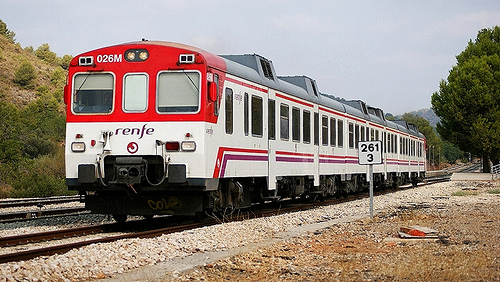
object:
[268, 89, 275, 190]
door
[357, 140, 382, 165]
sign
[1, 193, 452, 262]
tracks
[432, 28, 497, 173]
tree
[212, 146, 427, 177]
stripes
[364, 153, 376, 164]
3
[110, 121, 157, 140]
word "renfe"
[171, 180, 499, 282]
ground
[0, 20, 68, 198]
grassy hill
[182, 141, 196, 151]
headlight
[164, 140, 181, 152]
red light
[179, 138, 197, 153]
white light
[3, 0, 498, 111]
sky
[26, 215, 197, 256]
railroad tracks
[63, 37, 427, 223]
train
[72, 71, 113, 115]
windshield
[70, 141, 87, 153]
headlight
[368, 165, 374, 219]
metal pole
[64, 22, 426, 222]
train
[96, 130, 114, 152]
horn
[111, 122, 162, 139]
logo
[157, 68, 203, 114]
window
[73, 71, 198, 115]
window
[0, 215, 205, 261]
track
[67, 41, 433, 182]
train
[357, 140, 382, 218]
sign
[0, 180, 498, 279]
track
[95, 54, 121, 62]
print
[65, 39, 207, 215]
front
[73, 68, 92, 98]
wiper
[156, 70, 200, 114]
blinds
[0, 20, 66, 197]
hill